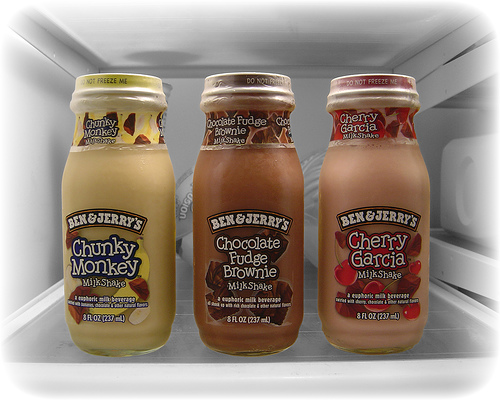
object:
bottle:
[190, 70, 305, 357]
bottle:
[317, 72, 428, 351]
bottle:
[61, 73, 176, 357]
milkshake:
[62, 113, 176, 351]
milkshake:
[193, 103, 306, 353]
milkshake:
[319, 103, 431, 352]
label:
[64, 207, 151, 328]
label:
[334, 205, 422, 321]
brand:
[66, 207, 149, 242]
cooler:
[6, 4, 496, 386]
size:
[81, 313, 126, 325]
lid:
[72, 72, 165, 98]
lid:
[201, 71, 293, 96]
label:
[204, 209, 293, 325]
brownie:
[251, 280, 293, 326]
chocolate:
[395, 271, 421, 306]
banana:
[88, 237, 149, 318]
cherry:
[333, 240, 358, 286]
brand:
[208, 209, 295, 239]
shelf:
[5, 252, 497, 376]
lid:
[328, 73, 422, 100]